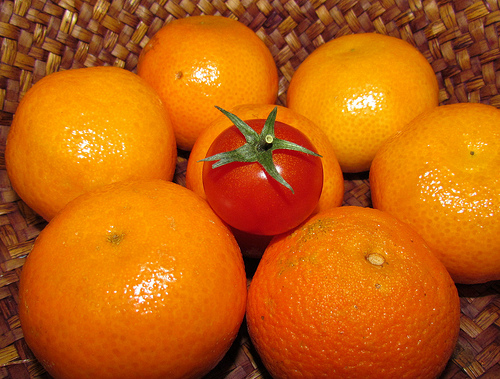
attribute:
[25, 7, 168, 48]
basket — wicker, brown, weaved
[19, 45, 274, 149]
oranges — seven, circle, tan, grouped, group, shiny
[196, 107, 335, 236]
tomatoe — one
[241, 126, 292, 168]
stem — green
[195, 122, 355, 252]
tomato — red, round, shin, small, shiny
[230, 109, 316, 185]
leaf — green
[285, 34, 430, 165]
orange — bright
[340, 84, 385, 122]
glare — bright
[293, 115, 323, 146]
spot — brown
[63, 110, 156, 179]
shine — bright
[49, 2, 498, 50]
wicker — brown